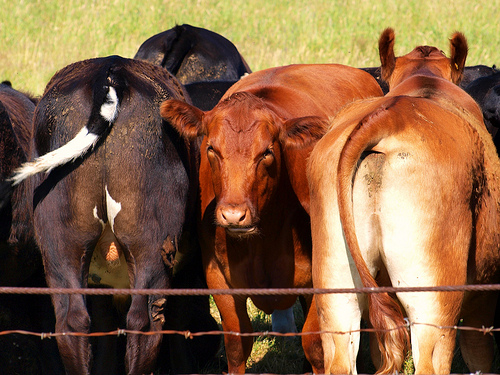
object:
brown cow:
[159, 64, 387, 375]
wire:
[1, 317, 498, 340]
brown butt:
[309, 96, 466, 285]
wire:
[5, 279, 499, 296]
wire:
[2, 321, 499, 338]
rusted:
[149, 329, 213, 339]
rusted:
[425, 283, 497, 293]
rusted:
[316, 327, 388, 334]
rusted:
[69, 331, 115, 339]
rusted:
[274, 331, 311, 340]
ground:
[361, 0, 395, 25]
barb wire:
[177, 287, 301, 297]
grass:
[3, 2, 485, 103]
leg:
[300, 181, 368, 371]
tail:
[333, 103, 410, 374]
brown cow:
[298, 28, 499, 375]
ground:
[194, 285, 314, 373]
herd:
[0, 22, 500, 374]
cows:
[7, 54, 196, 374]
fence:
[134, 286, 486, 337]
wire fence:
[4, 320, 498, 344]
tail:
[5, 71, 122, 187]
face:
[206, 110, 282, 239]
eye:
[262, 149, 272, 157]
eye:
[207, 145, 214, 151]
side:
[352, 194, 369, 275]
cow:
[132, 23, 252, 111]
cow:
[0, 75, 38, 372]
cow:
[157, 63, 385, 375]